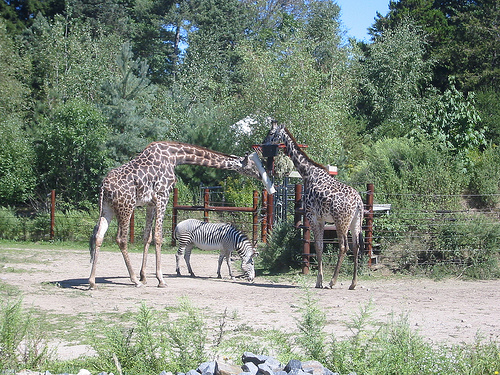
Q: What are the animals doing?
A: Eating.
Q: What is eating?
A: Animals.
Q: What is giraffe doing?
A: Eating.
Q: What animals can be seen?
A: Zebra and Giraffe.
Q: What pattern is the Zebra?
A: Striped.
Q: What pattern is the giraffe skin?
A: Spotted.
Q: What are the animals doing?
A: Eating.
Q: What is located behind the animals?
A: Trees.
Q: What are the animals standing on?
A: Dirt.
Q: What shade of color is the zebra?
A: Black and white.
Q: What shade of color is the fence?
A: Brown.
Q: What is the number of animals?
A: 3.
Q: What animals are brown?
A: Giraffes.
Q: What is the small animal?
A: Zebra.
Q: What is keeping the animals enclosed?
A: The fence.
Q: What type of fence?
A: Wood and wire.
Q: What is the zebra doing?
A: Grazing.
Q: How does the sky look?
A: Blue and clear.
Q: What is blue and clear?
A: The sky.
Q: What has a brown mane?
A: Giraffe.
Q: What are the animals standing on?
A: Dirt.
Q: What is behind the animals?
A: Trees.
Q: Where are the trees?
A: Behind the animals.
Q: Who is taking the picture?
A: The groundskeeper.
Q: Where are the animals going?
A: To find water.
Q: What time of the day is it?
A: Noon.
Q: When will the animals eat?
A: In two hours.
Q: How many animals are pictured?
A: 3.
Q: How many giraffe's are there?
A: 2.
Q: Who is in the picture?
A: No one.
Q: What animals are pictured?
A: Giraffe's and a zebra.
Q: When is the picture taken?
A: Daytime.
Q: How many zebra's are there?
A: 1.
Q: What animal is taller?
A: The giraffe.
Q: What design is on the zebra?
A: Stripes.